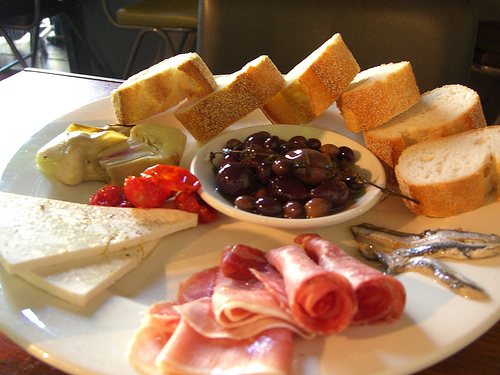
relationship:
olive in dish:
[287, 201, 302, 217] [190, 124, 385, 227]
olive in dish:
[304, 197, 331, 216] [190, 124, 385, 227]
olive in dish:
[219, 165, 255, 195] [190, 124, 385, 227]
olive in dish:
[319, 144, 340, 156] [190, 124, 385, 227]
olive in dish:
[292, 137, 307, 145] [190, 124, 385, 227]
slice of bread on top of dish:
[113, 52, 219, 125] [1, 75, 499, 373]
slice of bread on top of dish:
[174, 56, 287, 146] [1, 75, 499, 373]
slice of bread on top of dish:
[260, 33, 361, 125] [1, 75, 499, 373]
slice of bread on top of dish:
[337, 61, 422, 132] [1, 75, 499, 373]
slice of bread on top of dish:
[363, 84, 487, 169] [1, 75, 499, 373]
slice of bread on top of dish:
[394, 126, 499, 219] [1, 75, 499, 373]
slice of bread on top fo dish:
[113, 52, 219, 125] [1, 75, 499, 373]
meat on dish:
[133, 234, 406, 374] [1, 75, 499, 373]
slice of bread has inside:
[394, 126, 499, 219] [402, 129, 499, 183]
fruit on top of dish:
[90, 164, 222, 225] [1, 75, 499, 373]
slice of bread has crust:
[113, 52, 219, 125] [113, 58, 219, 125]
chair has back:
[104, 0, 199, 80] [102, 0, 119, 28]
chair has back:
[0, 1, 108, 77] [34, 0, 82, 18]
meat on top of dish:
[133, 234, 406, 374] [1, 75, 499, 373]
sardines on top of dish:
[351, 224, 499, 302] [1, 75, 499, 373]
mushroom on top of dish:
[98, 124, 186, 186] [1, 75, 499, 373]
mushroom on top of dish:
[36, 124, 137, 186] [1, 75, 499, 373]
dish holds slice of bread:
[1, 75, 499, 373] [260, 33, 361, 125]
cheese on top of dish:
[0, 189, 199, 273] [1, 75, 499, 373]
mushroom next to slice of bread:
[98, 124, 186, 186] [113, 52, 219, 125]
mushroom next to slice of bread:
[36, 124, 137, 186] [113, 52, 219, 125]